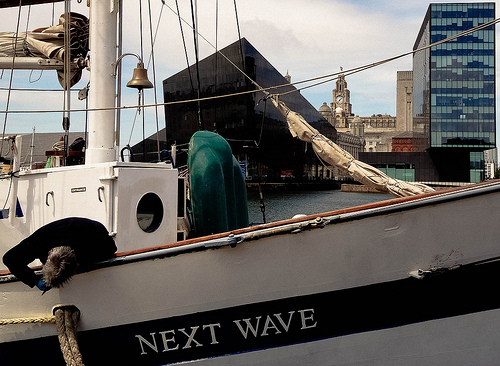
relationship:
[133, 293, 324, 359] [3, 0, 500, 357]
writing on boat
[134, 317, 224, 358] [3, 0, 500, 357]
word on boat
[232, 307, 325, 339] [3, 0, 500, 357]
word on boat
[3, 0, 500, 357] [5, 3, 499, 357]
boat has part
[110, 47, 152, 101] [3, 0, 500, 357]
bell on boat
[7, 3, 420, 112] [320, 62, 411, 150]
clouds above land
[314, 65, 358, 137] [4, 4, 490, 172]
building in background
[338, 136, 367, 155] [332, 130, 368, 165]
windows on building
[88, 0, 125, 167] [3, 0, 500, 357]
pole on boat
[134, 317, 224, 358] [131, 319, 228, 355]
word in letters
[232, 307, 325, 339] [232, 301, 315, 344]
word has lettering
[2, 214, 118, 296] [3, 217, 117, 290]
man in black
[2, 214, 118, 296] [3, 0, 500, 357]
man bent over boat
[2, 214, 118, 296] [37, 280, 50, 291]
man with glove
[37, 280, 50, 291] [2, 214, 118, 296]
glove on man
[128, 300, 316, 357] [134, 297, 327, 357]
next wave in letters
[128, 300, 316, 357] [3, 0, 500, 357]
next wave on boat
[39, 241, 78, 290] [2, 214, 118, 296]
hair on man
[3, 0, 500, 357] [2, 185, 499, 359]
boat has side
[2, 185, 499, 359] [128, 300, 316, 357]
side says next wave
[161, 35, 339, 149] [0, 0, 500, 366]
building past boat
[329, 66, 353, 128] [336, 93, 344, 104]
clock tower with clock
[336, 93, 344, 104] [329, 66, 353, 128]
clock on clock tower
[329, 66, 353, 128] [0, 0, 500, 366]
clock tower past boat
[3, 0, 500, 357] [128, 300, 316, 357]
boat says next wave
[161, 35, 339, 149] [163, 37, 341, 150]
building made of glass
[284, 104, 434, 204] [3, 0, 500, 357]
mast on boat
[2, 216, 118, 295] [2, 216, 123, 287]
man in jacket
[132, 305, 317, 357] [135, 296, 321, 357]
next wave says next wave